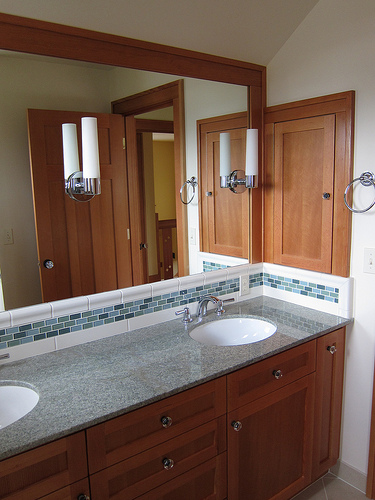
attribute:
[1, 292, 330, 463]
sinks — white, grey, marble, recessed, mounted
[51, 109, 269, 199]
wall sconces — mounted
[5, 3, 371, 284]
mirror — mounted, frame, large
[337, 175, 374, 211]
towel ring — mounted, chrome, hanging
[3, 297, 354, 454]
vanity top — marble, grey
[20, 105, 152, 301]
door — open, reflected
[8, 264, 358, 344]
tile — backsplashed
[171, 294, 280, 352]
sink — recessed, white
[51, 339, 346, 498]
knobs — glass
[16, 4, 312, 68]
ceiling — slanted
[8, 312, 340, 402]
counter top — marble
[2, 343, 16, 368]
outlet — electrical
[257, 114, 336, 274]
cabinet door — brown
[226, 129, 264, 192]
light — connected, reflected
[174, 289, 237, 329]
faucet — silver, chrome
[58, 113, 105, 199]
light — reflected